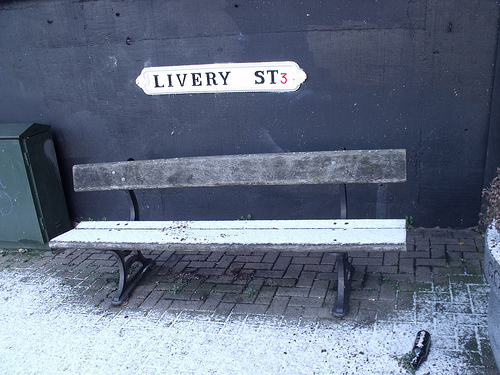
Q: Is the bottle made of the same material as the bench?
A: No, the bottle is made of glass and the bench is made of wood.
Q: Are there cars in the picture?
A: No, there are no cars.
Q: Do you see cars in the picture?
A: No, there are no cars.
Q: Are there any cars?
A: No, there are no cars.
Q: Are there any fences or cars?
A: No, there are no cars or fences.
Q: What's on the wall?
A: The sign is on the wall.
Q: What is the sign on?
A: The sign is on the wall.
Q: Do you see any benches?
A: Yes, there is a bench.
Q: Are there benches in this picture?
A: Yes, there is a bench.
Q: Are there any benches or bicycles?
A: Yes, there is a bench.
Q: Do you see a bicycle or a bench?
A: Yes, there is a bench.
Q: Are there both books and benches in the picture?
A: No, there is a bench but no books.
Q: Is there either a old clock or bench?
A: Yes, there is an old bench.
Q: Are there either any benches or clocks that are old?
A: Yes, the bench is old.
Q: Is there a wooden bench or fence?
A: Yes, there is a wood bench.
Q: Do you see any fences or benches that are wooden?
A: Yes, the bench is wooden.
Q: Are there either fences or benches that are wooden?
A: Yes, the bench is wooden.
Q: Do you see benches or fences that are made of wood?
A: Yes, the bench is made of wood.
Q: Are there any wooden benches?
A: Yes, there is a wood bench.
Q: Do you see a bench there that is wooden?
A: Yes, there is a bench that is wooden.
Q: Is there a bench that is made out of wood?
A: Yes, there is a bench that is made of wood.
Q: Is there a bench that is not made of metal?
A: Yes, there is a bench that is made of wood.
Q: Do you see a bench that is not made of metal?
A: Yes, there is a bench that is made of wood.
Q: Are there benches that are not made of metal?
A: Yes, there is a bench that is made of wood.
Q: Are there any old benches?
A: Yes, there is an old bench.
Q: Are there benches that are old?
A: Yes, there is a bench that is old.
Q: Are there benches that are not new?
A: Yes, there is a old bench.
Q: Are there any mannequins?
A: No, there are no mannequins.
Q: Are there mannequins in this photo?
A: No, there are no mannequins.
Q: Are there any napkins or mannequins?
A: No, there are no mannequins or napkins.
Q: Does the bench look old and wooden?
A: Yes, the bench is old and wooden.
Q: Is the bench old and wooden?
A: Yes, the bench is old and wooden.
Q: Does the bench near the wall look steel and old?
A: No, the bench is old but wooden.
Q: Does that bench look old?
A: Yes, the bench is old.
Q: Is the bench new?
A: No, the bench is old.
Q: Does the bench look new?
A: No, the bench is old.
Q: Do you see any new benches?
A: No, there is a bench but it is old.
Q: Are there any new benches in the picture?
A: No, there is a bench but it is old.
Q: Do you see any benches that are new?
A: No, there is a bench but it is old.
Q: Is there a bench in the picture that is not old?
A: No, there is a bench but it is old.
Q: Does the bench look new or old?
A: The bench is old.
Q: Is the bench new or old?
A: The bench is old.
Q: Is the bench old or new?
A: The bench is old.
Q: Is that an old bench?
A: Yes, that is an old bench.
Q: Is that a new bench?
A: No, that is an old bench.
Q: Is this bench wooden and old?
A: Yes, the bench is wooden and old.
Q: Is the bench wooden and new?
A: No, the bench is wooden but old.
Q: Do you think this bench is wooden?
A: Yes, the bench is wooden.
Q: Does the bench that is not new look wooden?
A: Yes, the bench is wooden.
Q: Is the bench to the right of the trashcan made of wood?
A: Yes, the bench is made of wood.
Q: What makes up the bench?
A: The bench is made of wood.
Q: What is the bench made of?
A: The bench is made of wood.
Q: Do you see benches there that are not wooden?
A: No, there is a bench but it is wooden.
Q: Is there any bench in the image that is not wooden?
A: No, there is a bench but it is wooden.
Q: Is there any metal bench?
A: No, there is a bench but it is made of wood.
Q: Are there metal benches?
A: No, there is a bench but it is made of wood.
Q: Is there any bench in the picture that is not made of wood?
A: No, there is a bench but it is made of wood.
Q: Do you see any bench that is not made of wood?
A: No, there is a bench but it is made of wood.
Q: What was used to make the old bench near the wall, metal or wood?
A: The bench is made of wood.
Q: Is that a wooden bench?
A: Yes, that is a wooden bench.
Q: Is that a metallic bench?
A: No, that is a wooden bench.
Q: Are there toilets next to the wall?
A: No, there is a bench next to the wall.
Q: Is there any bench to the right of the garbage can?
A: Yes, there is a bench to the right of the garbage can.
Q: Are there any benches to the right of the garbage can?
A: Yes, there is a bench to the right of the garbage can.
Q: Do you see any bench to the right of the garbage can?
A: Yes, there is a bench to the right of the garbage can.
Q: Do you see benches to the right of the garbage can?
A: Yes, there is a bench to the right of the garbage can.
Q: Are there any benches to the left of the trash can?
A: No, the bench is to the right of the trash can.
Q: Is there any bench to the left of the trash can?
A: No, the bench is to the right of the trash can.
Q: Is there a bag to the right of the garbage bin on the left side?
A: No, there is a bench to the right of the trash bin.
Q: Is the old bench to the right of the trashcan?
A: Yes, the bench is to the right of the trashcan.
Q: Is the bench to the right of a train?
A: No, the bench is to the right of the trashcan.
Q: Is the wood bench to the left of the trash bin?
A: No, the bench is to the right of the trash bin.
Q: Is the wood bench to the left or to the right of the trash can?
A: The bench is to the right of the trash can.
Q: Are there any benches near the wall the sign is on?
A: Yes, there is a bench near the wall.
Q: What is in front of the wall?
A: The bench is in front of the wall.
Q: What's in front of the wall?
A: The bench is in front of the wall.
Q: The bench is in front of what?
A: The bench is in front of the wall.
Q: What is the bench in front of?
A: The bench is in front of the wall.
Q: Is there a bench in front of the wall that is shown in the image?
A: Yes, there is a bench in front of the wall.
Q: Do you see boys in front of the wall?
A: No, there is a bench in front of the wall.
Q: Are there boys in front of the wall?
A: No, there is a bench in front of the wall.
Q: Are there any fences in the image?
A: No, there are no fences.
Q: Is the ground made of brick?
A: Yes, the ground is made of brick.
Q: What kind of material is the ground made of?
A: The ground is made of brick.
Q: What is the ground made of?
A: The ground is made of brick.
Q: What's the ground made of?
A: The ground is made of brick.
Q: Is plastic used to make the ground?
A: No, the ground is made of brick.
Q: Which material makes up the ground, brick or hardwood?
A: The ground is made of brick.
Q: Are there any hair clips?
A: No, there are no hair clips.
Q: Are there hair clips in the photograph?
A: No, there are no hair clips.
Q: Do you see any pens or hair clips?
A: No, there are no hair clips or pens.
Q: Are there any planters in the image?
A: No, there are no planters.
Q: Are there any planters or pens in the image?
A: No, there are no planters or pens.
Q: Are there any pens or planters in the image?
A: No, there are no planters or pens.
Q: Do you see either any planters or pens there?
A: No, there are no planters or pens.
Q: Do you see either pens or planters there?
A: No, there are no planters or pens.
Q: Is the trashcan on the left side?
A: Yes, the trashcan is on the left of the image.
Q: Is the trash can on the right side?
A: No, the trash can is on the left of the image.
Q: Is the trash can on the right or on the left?
A: The trash can is on the left of the image.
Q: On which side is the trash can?
A: The trash can is on the left of the image.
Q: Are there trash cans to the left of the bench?
A: Yes, there is a trash can to the left of the bench.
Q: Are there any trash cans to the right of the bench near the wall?
A: No, the trash can is to the left of the bench.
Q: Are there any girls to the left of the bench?
A: No, there is a trash can to the left of the bench.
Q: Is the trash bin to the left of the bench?
A: Yes, the trash bin is to the left of the bench.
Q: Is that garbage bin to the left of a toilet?
A: No, the garbage bin is to the left of the bench.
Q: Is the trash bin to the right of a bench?
A: No, the trash bin is to the left of a bench.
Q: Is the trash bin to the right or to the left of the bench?
A: The trash bin is to the left of the bench.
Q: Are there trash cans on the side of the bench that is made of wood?
A: Yes, there is a trash can on the side of the bench.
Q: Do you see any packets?
A: No, there are no packets.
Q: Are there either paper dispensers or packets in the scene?
A: No, there are no packets or paper dispensers.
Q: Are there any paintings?
A: No, there are no paintings.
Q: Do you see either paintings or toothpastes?
A: No, there are no paintings or toothpastes.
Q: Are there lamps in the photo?
A: No, there are no lamps.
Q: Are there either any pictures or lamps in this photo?
A: No, there are no lamps or pictures.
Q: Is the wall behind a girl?
A: No, the wall is behind the bench.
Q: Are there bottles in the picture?
A: Yes, there is a bottle.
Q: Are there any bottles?
A: Yes, there is a bottle.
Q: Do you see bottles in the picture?
A: Yes, there is a bottle.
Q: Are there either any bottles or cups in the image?
A: Yes, there is a bottle.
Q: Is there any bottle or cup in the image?
A: Yes, there is a bottle.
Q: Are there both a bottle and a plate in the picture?
A: No, there is a bottle but no plates.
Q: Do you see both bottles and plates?
A: No, there is a bottle but no plates.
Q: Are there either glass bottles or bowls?
A: Yes, there is a glass bottle.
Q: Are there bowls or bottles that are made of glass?
A: Yes, the bottle is made of glass.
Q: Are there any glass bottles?
A: Yes, there is a bottle that is made of glass.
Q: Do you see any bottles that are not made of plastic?
A: Yes, there is a bottle that is made of glass.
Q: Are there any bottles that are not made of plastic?
A: Yes, there is a bottle that is made of glass.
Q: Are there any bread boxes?
A: No, there are no bread boxes.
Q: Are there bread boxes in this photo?
A: No, there are no bread boxes.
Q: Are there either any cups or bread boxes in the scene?
A: No, there are no bread boxes or cups.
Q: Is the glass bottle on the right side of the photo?
A: Yes, the bottle is on the right of the image.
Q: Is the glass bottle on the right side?
A: Yes, the bottle is on the right of the image.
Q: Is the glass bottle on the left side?
A: No, the bottle is on the right of the image.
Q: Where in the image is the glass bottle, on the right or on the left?
A: The bottle is on the right of the image.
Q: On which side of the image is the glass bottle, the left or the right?
A: The bottle is on the right of the image.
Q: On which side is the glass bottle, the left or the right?
A: The bottle is on the right of the image.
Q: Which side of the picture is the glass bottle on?
A: The bottle is on the right of the image.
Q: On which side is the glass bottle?
A: The bottle is on the right of the image.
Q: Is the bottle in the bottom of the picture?
A: Yes, the bottle is in the bottom of the image.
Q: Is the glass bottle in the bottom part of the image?
A: Yes, the bottle is in the bottom of the image.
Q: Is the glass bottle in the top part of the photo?
A: No, the bottle is in the bottom of the image.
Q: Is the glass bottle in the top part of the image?
A: No, the bottle is in the bottom of the image.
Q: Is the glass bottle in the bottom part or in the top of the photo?
A: The bottle is in the bottom of the image.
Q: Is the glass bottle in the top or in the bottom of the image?
A: The bottle is in the bottom of the image.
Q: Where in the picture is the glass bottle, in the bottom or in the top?
A: The bottle is in the bottom of the image.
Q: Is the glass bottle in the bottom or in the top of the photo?
A: The bottle is in the bottom of the image.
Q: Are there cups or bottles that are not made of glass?
A: No, there is a bottle but it is made of glass.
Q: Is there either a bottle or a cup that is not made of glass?
A: No, there is a bottle but it is made of glass.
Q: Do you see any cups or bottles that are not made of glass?
A: No, there is a bottle but it is made of glass.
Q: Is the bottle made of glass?
A: Yes, the bottle is made of glass.